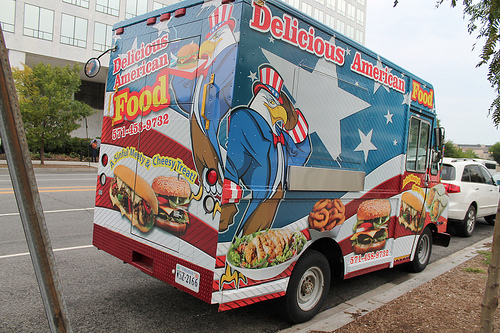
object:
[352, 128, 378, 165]
star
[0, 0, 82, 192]
background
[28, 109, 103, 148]
wall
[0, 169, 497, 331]
roadway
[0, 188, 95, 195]
stripes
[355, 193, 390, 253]
hamburger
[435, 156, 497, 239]
car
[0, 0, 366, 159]
building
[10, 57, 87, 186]
tree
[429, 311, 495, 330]
dirt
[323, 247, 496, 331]
ground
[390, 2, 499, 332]
tree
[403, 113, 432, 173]
window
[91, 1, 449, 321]
food truck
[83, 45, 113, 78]
convex mirror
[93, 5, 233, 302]
back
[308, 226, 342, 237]
container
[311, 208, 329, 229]
onion rings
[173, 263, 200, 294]
plate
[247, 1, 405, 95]
sign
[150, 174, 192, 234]
burger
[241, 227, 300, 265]
grilled chicken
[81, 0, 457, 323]
truck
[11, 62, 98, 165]
green tree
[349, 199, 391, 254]
cheeseburger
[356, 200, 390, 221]
bun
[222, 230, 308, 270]
green salad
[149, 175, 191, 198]
sesame roll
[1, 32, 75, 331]
pole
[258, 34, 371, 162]
stars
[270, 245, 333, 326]
wheel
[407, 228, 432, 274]
wheel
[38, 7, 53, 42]
windows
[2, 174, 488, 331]
street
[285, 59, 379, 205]
window